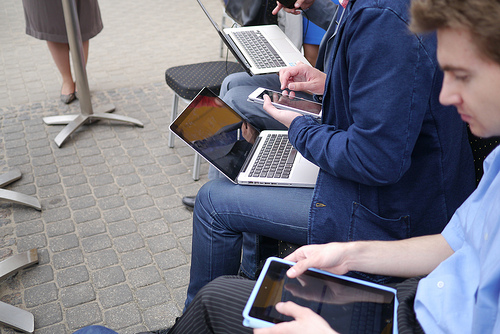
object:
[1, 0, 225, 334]
sidewalk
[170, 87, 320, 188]
computer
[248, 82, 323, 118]
computer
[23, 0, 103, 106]
woman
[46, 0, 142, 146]
lectern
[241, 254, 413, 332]
tablet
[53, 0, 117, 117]
legs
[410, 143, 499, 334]
shirt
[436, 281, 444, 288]
button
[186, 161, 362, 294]
jeans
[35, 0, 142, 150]
stand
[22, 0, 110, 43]
skirt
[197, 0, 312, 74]
computer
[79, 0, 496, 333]
human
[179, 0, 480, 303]
human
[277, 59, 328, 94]
hand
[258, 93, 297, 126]
hand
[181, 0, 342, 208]
human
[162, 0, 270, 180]
chair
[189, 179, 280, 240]
lap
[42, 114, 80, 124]
leg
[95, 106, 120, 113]
leg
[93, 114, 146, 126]
leg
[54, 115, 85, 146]
leg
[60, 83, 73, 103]
shoe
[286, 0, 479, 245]
jacket